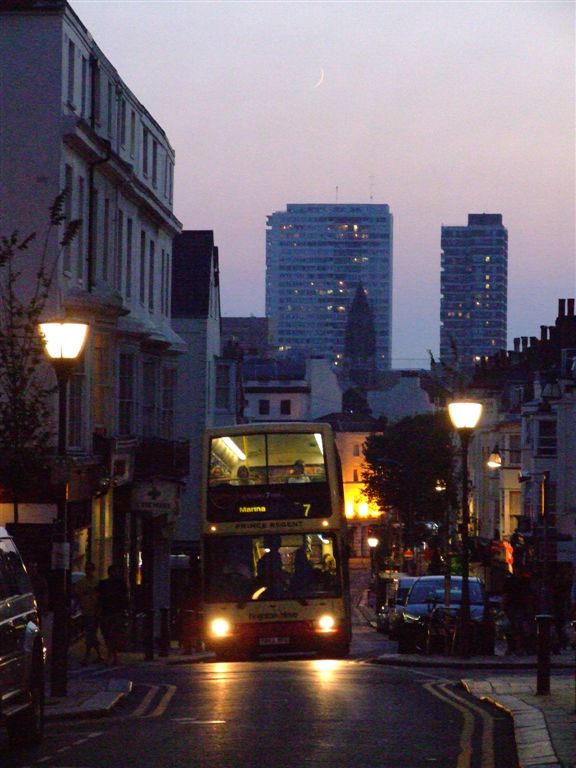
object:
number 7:
[303, 503, 311, 516]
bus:
[190, 422, 357, 659]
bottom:
[202, 531, 349, 657]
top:
[202, 421, 340, 532]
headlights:
[314, 611, 339, 633]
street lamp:
[448, 401, 482, 656]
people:
[75, 561, 124, 665]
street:
[49, 624, 513, 767]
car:
[398, 575, 496, 657]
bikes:
[418, 595, 477, 658]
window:
[120, 349, 132, 435]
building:
[0, 0, 187, 649]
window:
[66, 350, 85, 452]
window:
[94, 334, 109, 437]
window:
[143, 360, 154, 436]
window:
[161, 362, 174, 441]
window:
[66, 164, 73, 272]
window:
[79, 175, 82, 285]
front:
[203, 599, 349, 658]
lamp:
[448, 401, 483, 431]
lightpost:
[457, 427, 474, 659]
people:
[288, 458, 313, 483]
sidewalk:
[42, 658, 205, 716]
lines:
[420, 678, 496, 768]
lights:
[345, 496, 384, 518]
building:
[314, 386, 389, 570]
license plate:
[260, 636, 291, 645]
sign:
[130, 480, 179, 512]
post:
[143, 510, 155, 662]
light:
[38, 321, 88, 359]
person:
[257, 534, 282, 580]